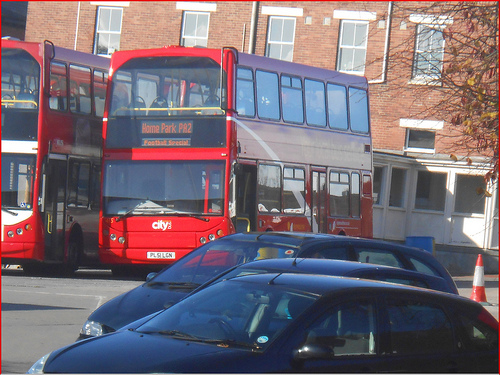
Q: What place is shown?
A: It is a parking lot.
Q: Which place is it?
A: It is a parking lot.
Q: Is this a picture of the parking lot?
A: Yes, it is showing the parking lot.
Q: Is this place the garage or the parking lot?
A: It is the parking lot.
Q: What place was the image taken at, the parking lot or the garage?
A: It was taken at the parking lot.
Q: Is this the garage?
A: No, it is the parking lot.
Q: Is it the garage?
A: No, it is the parking lot.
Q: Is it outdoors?
A: Yes, it is outdoors.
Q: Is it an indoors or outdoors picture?
A: It is outdoors.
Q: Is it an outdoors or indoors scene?
A: It is outdoors.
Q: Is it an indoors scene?
A: No, it is outdoors.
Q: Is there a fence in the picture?
A: No, there are no fences.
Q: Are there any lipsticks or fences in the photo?
A: No, there are no fences or lipsticks.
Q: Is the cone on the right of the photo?
A: Yes, the cone is on the right of the image.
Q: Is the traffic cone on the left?
A: No, the traffic cone is on the right of the image.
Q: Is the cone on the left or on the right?
A: The cone is on the right of the image.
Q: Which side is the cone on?
A: The cone is on the right of the image.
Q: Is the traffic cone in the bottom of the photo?
A: Yes, the traffic cone is in the bottom of the image.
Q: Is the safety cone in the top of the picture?
A: No, the safety cone is in the bottom of the image.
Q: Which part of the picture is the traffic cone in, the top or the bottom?
A: The traffic cone is in the bottom of the image.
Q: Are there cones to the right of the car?
A: Yes, there is a cone to the right of the car.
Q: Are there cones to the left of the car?
A: No, the cone is to the right of the car.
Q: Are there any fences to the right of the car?
A: No, there is a cone to the right of the car.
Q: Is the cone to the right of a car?
A: Yes, the cone is to the right of a car.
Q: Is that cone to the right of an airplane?
A: No, the cone is to the right of a car.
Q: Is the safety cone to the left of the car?
A: No, the safety cone is to the right of the car.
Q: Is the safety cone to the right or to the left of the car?
A: The safety cone is to the right of the car.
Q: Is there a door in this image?
A: Yes, there is a door.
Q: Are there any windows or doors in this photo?
A: Yes, there is a door.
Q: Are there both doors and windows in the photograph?
A: Yes, there are both a door and windows.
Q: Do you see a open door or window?
A: Yes, there is an open door.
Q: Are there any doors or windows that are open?
A: Yes, the door is open.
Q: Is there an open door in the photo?
A: Yes, there is an open door.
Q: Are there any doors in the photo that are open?
A: Yes, there is a door that is open.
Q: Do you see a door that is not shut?
A: Yes, there is a open door.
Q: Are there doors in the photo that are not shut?
A: Yes, there is a open door.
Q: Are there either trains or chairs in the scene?
A: No, there are no trains or chairs.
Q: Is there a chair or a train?
A: No, there are no trains or chairs.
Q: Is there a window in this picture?
A: Yes, there is a window.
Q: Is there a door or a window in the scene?
A: Yes, there is a window.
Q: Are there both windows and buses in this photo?
A: Yes, there are both a window and a bus.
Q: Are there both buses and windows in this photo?
A: Yes, there are both a window and a bus.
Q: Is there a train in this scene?
A: No, there are no trains.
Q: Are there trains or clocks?
A: No, there are no trains or clocks.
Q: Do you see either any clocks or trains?
A: No, there are no trains or clocks.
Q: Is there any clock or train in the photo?
A: No, there are no trains or clocks.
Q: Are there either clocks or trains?
A: No, there are no trains or clocks.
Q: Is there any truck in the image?
A: No, there are no trucks.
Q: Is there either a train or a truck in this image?
A: No, there are no trucks or trains.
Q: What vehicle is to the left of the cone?
A: The vehicle is a car.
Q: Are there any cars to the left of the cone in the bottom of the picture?
A: Yes, there is a car to the left of the cone.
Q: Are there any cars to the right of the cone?
A: No, the car is to the left of the cone.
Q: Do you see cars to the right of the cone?
A: No, the car is to the left of the cone.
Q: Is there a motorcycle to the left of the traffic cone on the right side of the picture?
A: No, there is a car to the left of the traffic cone.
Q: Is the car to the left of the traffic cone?
A: Yes, the car is to the left of the traffic cone.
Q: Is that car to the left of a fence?
A: No, the car is to the left of the traffic cone.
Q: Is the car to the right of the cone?
A: No, the car is to the left of the cone.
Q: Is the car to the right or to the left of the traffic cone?
A: The car is to the left of the traffic cone.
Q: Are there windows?
A: Yes, there is a window.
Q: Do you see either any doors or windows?
A: Yes, there is a window.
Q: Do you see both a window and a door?
A: Yes, there are both a window and a door.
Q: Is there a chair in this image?
A: No, there are no chairs.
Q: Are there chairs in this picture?
A: No, there are no chairs.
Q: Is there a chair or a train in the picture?
A: No, there are no chairs or trains.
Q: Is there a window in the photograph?
A: Yes, there is a window.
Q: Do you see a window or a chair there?
A: Yes, there is a window.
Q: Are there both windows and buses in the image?
A: Yes, there are both a window and a bus.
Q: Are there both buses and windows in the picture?
A: Yes, there are both a window and a bus.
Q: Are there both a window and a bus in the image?
A: Yes, there are both a window and a bus.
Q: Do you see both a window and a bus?
A: Yes, there are both a window and a bus.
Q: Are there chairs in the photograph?
A: No, there are no chairs.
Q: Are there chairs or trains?
A: No, there are no chairs or trains.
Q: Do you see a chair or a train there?
A: No, there are no chairs or trains.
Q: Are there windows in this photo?
A: Yes, there is a window.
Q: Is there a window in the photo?
A: Yes, there is a window.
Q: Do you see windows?
A: Yes, there is a window.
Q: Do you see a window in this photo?
A: Yes, there is a window.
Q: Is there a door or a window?
A: Yes, there is a window.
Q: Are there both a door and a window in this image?
A: Yes, there are both a window and a door.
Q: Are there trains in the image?
A: No, there are no trains.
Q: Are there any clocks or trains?
A: No, there are no trains or clocks.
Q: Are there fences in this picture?
A: No, there are no fences.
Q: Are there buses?
A: Yes, there is a bus.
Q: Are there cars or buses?
A: Yes, there is a bus.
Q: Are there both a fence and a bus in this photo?
A: No, there is a bus but no fences.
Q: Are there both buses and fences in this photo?
A: No, there is a bus but no fences.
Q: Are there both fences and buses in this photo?
A: No, there is a bus but no fences.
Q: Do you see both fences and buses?
A: No, there is a bus but no fences.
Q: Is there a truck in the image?
A: No, there are no trucks.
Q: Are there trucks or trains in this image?
A: No, there are no trucks or trains.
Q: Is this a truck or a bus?
A: This is a bus.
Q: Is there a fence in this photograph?
A: No, there are no fences.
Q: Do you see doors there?
A: Yes, there is a door.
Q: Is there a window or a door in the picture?
A: Yes, there is a door.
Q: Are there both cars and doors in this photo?
A: Yes, there are both a door and a car.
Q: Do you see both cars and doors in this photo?
A: Yes, there are both a door and a car.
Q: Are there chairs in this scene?
A: No, there are no chairs.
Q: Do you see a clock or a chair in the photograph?
A: No, there are no chairs or clocks.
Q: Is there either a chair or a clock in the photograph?
A: No, there are no chairs or clocks.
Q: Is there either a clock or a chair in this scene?
A: No, there are no chairs or clocks.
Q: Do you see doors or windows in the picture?
A: Yes, there is a window.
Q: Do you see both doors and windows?
A: Yes, there are both a window and doors.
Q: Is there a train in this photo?
A: No, there are no trains.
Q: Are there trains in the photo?
A: No, there are no trains.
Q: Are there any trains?
A: No, there are no trains.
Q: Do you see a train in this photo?
A: No, there are no trains.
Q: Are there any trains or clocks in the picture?
A: No, there are no trains or clocks.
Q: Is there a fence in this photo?
A: No, there are no fences.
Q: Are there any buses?
A: Yes, there is a bus.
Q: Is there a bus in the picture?
A: Yes, there is a bus.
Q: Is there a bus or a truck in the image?
A: Yes, there is a bus.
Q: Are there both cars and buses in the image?
A: Yes, there are both a bus and a car.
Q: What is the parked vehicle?
A: The vehicle is a bus.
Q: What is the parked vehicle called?
A: The vehicle is a bus.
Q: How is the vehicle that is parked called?
A: The vehicle is a bus.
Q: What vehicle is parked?
A: The vehicle is a bus.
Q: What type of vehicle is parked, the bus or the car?
A: The bus is parked.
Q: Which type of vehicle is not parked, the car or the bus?
A: The car is not parked.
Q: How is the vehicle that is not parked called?
A: The vehicle is a car.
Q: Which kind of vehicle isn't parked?
A: The vehicle is a car.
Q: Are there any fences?
A: No, there are no fences.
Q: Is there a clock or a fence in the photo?
A: No, there are no fences or clocks.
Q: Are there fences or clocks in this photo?
A: No, there are no fences or clocks.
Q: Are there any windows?
A: Yes, there are windows.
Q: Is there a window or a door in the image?
A: Yes, there are windows.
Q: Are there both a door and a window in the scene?
A: Yes, there are both a window and a door.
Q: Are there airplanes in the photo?
A: No, there are no airplanes.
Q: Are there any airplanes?
A: No, there are no airplanes.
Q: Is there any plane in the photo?
A: No, there are no airplanes.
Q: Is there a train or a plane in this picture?
A: No, there are no airplanes or trains.